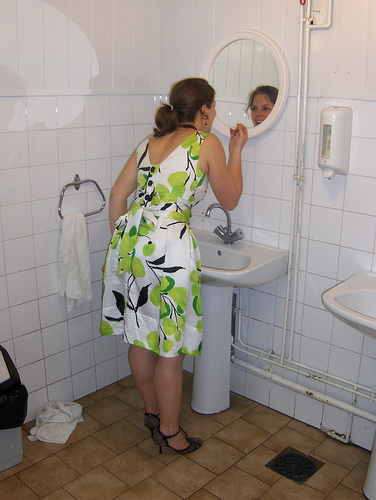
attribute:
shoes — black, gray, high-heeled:
[137, 408, 210, 463]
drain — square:
[262, 435, 334, 490]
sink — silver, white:
[189, 199, 291, 300]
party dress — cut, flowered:
[90, 125, 214, 358]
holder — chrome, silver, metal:
[48, 167, 111, 219]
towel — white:
[52, 202, 97, 314]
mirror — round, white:
[198, 27, 304, 145]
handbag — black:
[2, 338, 36, 430]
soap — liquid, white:
[316, 134, 341, 182]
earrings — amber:
[198, 114, 215, 129]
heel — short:
[151, 437, 168, 455]